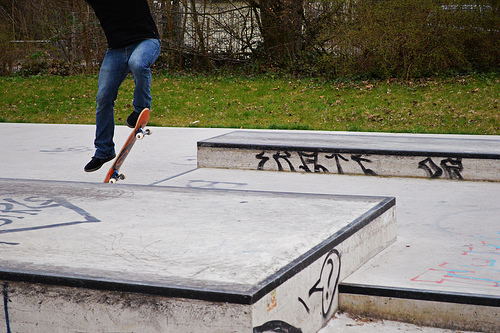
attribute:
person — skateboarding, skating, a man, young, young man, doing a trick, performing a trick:
[85, 1, 162, 171]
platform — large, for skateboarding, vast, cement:
[197, 130, 500, 181]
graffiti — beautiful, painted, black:
[257, 151, 376, 174]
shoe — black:
[85, 150, 118, 171]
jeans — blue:
[95, 38, 160, 159]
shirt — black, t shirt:
[85, 1, 160, 48]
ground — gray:
[2, 74, 500, 332]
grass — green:
[0, 75, 499, 134]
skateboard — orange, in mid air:
[105, 107, 154, 184]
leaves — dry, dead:
[332, 77, 469, 94]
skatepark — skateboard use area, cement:
[2, 122, 500, 331]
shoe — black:
[127, 108, 140, 127]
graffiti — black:
[298, 248, 343, 319]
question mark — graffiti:
[327, 259, 335, 299]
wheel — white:
[134, 131, 143, 140]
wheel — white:
[146, 128, 153, 135]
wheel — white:
[109, 178, 116, 185]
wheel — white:
[120, 172, 125, 180]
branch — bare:
[172, 7, 257, 16]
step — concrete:
[0, 176, 398, 329]